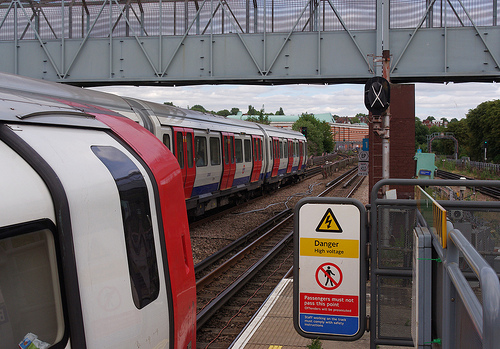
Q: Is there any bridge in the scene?
A: Yes, there is a bridge.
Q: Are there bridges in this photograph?
A: Yes, there is a bridge.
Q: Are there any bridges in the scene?
A: Yes, there is a bridge.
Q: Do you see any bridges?
A: Yes, there is a bridge.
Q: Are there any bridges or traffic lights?
A: Yes, there is a bridge.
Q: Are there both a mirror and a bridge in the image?
A: No, there is a bridge but no mirrors.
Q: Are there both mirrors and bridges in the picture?
A: No, there is a bridge but no mirrors.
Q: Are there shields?
A: No, there are no shields.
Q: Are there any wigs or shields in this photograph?
A: No, there are no shields or wigs.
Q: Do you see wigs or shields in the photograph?
A: No, there are no shields or wigs.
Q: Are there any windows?
A: Yes, there is a window.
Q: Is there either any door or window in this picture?
A: Yes, there is a window.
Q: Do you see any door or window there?
A: Yes, there is a window.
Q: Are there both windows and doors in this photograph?
A: Yes, there are both a window and a door.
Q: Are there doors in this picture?
A: Yes, there is a door.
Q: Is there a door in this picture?
A: Yes, there is a door.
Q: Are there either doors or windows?
A: Yes, there is a door.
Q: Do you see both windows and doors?
A: Yes, there are both a door and windows.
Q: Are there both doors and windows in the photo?
A: Yes, there are both a door and windows.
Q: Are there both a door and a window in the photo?
A: Yes, there are both a door and a window.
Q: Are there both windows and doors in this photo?
A: Yes, there are both a door and windows.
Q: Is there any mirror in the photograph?
A: No, there are no mirrors.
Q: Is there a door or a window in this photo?
A: Yes, there is a window.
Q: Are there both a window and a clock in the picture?
A: No, there is a window but no clocks.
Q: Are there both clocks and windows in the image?
A: No, there is a window but no clocks.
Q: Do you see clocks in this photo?
A: No, there are no clocks.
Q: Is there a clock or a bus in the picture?
A: No, there are no clocks or buses.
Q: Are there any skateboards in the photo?
A: No, there are no skateboards.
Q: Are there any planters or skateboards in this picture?
A: No, there are no skateboards or planters.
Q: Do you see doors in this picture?
A: Yes, there is a door.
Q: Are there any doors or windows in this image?
A: Yes, there is a door.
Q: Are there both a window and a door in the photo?
A: Yes, there are both a door and a window.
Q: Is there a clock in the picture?
A: No, there are no clocks.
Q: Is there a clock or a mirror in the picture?
A: No, there are no clocks or mirrors.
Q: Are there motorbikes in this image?
A: No, there are no motorbikes.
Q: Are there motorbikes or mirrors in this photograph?
A: No, there are no motorbikes or mirrors.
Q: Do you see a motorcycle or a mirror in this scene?
A: No, there are no motorcycles or mirrors.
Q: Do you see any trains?
A: Yes, there is a train.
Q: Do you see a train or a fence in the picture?
A: Yes, there is a train.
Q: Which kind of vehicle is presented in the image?
A: The vehicle is a train.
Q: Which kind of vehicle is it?
A: The vehicle is a train.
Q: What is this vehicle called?
A: That is a train.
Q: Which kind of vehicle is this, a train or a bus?
A: That is a train.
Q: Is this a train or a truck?
A: This is a train.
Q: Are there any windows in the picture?
A: Yes, there is a window.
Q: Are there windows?
A: Yes, there is a window.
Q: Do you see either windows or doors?
A: Yes, there is a window.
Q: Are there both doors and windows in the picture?
A: Yes, there are both a window and a door.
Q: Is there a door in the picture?
A: Yes, there is a door.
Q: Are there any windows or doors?
A: Yes, there is a door.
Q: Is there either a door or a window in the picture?
A: Yes, there is a door.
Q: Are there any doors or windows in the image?
A: Yes, there is a door.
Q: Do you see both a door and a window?
A: Yes, there are both a door and a window.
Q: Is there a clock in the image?
A: No, there are no clocks.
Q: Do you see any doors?
A: Yes, there is a door.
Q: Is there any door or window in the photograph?
A: Yes, there is a door.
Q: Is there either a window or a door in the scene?
A: Yes, there is a door.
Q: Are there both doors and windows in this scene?
A: Yes, there are both a door and a window.